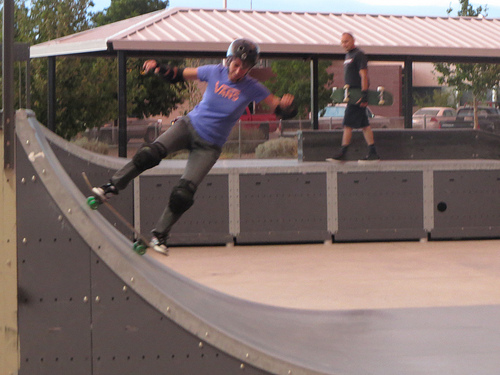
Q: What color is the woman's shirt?
A: Blue.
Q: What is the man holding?
A: A skateboard.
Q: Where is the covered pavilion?
A: Next to the skateboard ramp.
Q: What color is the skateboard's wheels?
A: Green.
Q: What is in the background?
A: Trees.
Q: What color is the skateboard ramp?
A: Gray.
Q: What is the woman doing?
A: Riding a skateboard.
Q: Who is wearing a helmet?
A: The woman.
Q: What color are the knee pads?
A: Black.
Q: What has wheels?
A: The skateboard.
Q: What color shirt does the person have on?
A: Blue.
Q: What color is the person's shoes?
A: Black and white.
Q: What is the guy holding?
A: Skateboard.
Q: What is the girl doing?
A: Skateboarding.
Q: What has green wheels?
A: The skateboard.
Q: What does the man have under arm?
A: Skateboard.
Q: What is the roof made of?
A: Metal.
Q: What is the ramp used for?
A: Skating.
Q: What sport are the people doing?
A: Skateboarding.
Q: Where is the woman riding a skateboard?
A: On a ramp.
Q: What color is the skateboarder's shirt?
A: Blue.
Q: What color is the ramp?
A: Gray.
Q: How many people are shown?
A: Two.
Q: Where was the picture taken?
A: A skateboard park.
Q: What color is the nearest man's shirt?
A: Blue.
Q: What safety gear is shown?
A: Knee pads, elbow pads and a helmet.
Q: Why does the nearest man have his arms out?
A: For balance.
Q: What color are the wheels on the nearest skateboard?
A: Green.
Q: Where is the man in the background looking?
A: At the other man.